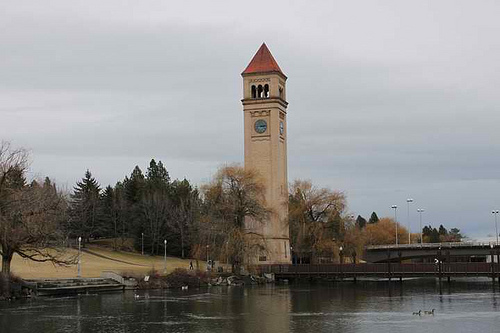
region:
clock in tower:
[248, 111, 276, 141]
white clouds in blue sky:
[11, 6, 52, 56]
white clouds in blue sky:
[10, 64, 44, 96]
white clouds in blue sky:
[37, 103, 69, 130]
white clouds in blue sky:
[61, 32, 117, 109]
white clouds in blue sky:
[96, 99, 136, 131]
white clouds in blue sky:
[127, 58, 176, 107]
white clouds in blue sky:
[300, 30, 340, 81]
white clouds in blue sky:
[318, 98, 360, 133]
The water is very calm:
[68, 299, 400, 328]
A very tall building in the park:
[236, 37, 296, 279]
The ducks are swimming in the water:
[398, 303, 450, 324]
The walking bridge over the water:
[272, 248, 497, 288]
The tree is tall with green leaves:
[51, 167, 193, 240]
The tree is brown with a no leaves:
[4, 166, 69, 307]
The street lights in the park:
[387, 189, 430, 242]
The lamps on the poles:
[385, 194, 430, 216]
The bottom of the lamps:
[391, 223, 427, 245]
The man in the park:
[181, 252, 204, 273]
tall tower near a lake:
[236, 38, 296, 272]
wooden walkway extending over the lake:
[243, 255, 498, 285]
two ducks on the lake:
[411, 304, 438, 320]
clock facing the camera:
[253, 118, 268, 136]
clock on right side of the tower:
[277, 118, 284, 139]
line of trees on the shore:
[4, 162, 464, 267]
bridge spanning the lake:
[356, 234, 499, 261]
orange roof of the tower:
[238, 38, 287, 79]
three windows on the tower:
[248, 80, 275, 102]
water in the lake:
[1, 268, 498, 332]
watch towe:
[220, 48, 303, 166]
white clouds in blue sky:
[12, 7, 63, 55]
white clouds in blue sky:
[20, 72, 83, 123]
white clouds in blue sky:
[67, 107, 118, 160]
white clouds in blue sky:
[67, 48, 109, 86]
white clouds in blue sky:
[114, 26, 162, 77]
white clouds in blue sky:
[281, 17, 350, 61]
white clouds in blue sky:
[342, 56, 446, 174]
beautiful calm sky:
[11, 5, 496, 240]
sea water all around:
[13, 271, 498, 331]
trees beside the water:
[4, 155, 464, 276]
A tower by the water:
[238, 43, 290, 263]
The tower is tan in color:
[241, 42, 296, 258]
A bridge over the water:
[247, 255, 497, 275]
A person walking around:
[185, 258, 198, 270]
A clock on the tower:
[253, 118, 269, 139]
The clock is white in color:
[248, 117, 270, 137]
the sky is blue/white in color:
[13, 5, 491, 235]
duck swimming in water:
[412, 306, 428, 320]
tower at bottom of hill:
[235, 39, 301, 270]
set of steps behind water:
[19, 271, 133, 296]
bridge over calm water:
[352, 229, 498, 267]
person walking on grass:
[187, 260, 194, 274]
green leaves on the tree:
[117, 196, 143, 216]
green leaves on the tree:
[127, 204, 159, 226]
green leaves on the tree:
[126, 131, 183, 217]